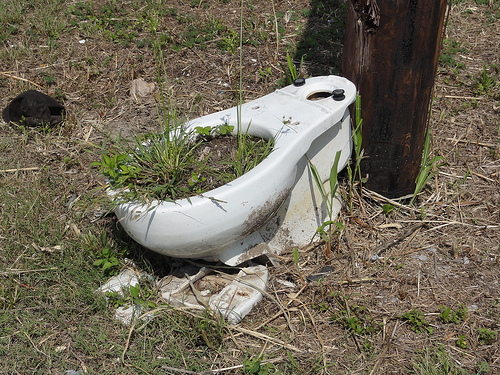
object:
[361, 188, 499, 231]
hay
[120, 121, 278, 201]
bowl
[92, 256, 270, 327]
toilet seat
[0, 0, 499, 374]
trash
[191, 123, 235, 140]
grass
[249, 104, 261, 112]
holes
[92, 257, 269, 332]
pieces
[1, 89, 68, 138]
rock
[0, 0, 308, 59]
grass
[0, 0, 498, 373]
field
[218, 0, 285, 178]
grass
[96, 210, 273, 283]
shadow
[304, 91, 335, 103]
hole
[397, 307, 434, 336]
grass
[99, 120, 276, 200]
weeds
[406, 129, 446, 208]
grass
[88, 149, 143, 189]
grass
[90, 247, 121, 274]
grass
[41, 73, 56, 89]
grass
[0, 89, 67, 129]
black item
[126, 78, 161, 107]
rock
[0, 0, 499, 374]
dirt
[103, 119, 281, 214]
toilet seat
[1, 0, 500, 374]
grassy patches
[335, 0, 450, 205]
pole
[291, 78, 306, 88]
screw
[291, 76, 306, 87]
bolt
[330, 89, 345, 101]
bolt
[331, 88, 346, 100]
screw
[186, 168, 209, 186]
grass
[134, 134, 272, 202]
dirt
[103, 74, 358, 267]
toilet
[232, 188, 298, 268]
dirt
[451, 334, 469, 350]
grass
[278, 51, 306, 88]
planter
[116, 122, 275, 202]
toilet bowl